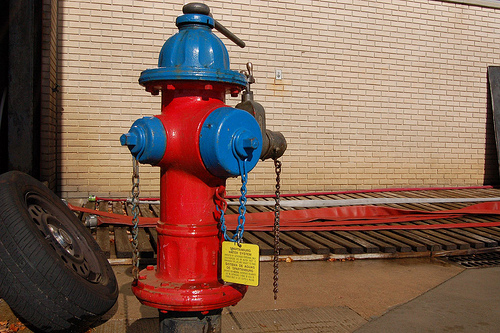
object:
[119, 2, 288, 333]
hydrant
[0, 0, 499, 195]
building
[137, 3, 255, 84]
top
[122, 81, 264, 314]
body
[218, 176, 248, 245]
chain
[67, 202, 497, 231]
hose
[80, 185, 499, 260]
pallet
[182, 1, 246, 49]
wrench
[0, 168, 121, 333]
tire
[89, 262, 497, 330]
sidewalk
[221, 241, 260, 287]
card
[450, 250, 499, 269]
grate